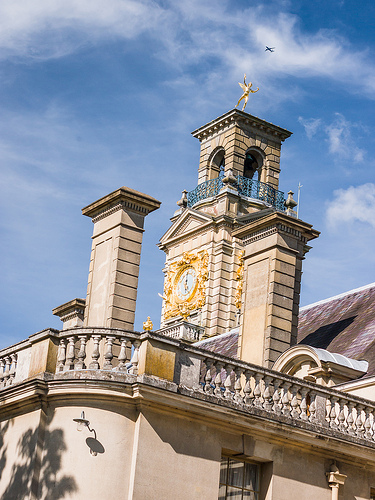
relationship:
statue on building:
[234, 72, 260, 110] [0, 58, 373, 498]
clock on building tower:
[160, 249, 212, 327] [149, 68, 317, 404]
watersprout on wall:
[326, 471, 349, 488] [279, 452, 333, 493]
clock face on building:
[165, 265, 203, 308] [0, 58, 373, 498]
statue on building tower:
[234, 72, 260, 110] [153, 106, 323, 376]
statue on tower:
[234, 72, 260, 110] [158, 109, 322, 373]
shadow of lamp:
[84, 423, 104, 455] [74, 408, 90, 431]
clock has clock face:
[172, 265, 196, 301] [175, 267, 197, 299]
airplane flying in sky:
[260, 42, 277, 55] [1, 0, 373, 353]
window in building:
[221, 449, 271, 498] [32, 116, 371, 493]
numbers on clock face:
[176, 268, 195, 299] [172, 266, 199, 304]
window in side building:
[221, 449, 259, 498] [0, 58, 373, 498]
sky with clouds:
[1, 0, 373, 353] [0, 0, 373, 240]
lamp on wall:
[74, 408, 90, 431] [86, 409, 120, 460]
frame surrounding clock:
[163, 252, 212, 316] [176, 267, 196, 299]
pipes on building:
[324, 461, 344, 497] [3, 99, 372, 493]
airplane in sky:
[264, 43, 278, 54] [1, 0, 373, 353]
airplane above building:
[264, 43, 278, 54] [0, 58, 373, 498]